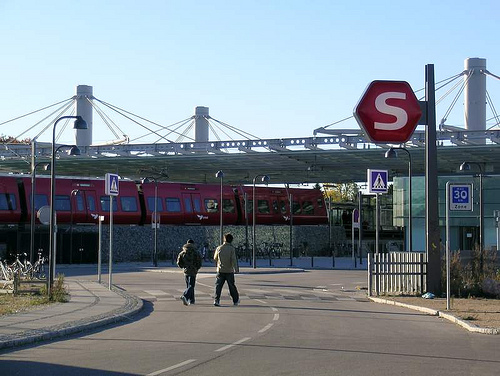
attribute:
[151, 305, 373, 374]
road — gray, grey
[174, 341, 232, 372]
lines — white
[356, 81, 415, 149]
sign — red, white, large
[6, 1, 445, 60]
sky — blue, clear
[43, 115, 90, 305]
lamp — tall, grey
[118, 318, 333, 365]
street — gray, cement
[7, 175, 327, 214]
train — red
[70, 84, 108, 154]
supports — grey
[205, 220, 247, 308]
man — walking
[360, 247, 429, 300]
fence — gray, white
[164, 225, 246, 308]
people — walking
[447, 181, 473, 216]
sign — blue, white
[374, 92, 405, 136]
s — large